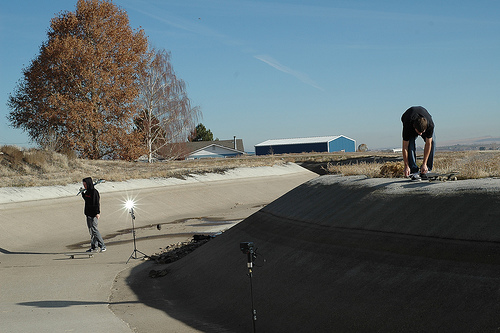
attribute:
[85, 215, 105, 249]
trousers — grey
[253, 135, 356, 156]
building — long, blue, small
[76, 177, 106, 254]
skateboarder — man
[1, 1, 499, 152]
sky — blue, here, clear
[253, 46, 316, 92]
clouds — white, wispy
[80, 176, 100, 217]
hoodie — black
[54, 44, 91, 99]
leaves — brown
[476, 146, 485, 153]
house — blue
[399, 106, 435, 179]
man — bending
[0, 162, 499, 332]
skate park — cement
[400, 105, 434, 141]
shirt — black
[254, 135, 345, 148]
roof — white